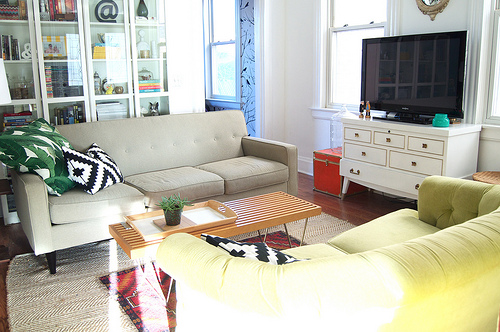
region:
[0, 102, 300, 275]
Pillows are on a couch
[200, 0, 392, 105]
Daylight coming from two windows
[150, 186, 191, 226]
A green plant in a pot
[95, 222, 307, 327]
A small rug on the floor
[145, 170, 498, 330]
A couch is lime green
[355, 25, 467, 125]
Reflections on a TV screen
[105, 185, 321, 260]
A brown wooden coffee table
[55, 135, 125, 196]
Pillow is black and white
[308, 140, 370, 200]
A red trunk on the floor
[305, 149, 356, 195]
orange trunk in the living room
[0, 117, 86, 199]
green and white throw pillow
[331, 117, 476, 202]
white dresser tv is on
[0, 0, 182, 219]
glass case shelving against the wall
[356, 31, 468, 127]
flatscreen tv with black frame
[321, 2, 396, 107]
white framed window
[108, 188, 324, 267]
coffee table between the couches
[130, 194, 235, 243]
tray on the coffee table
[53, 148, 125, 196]
black and white pillow on couch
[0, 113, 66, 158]
green and white pillow on couch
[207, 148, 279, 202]
cream seat cushion on couch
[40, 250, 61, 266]
black leg of couch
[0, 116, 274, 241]
large cream colored couch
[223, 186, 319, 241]
brown coffee table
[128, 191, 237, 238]
brown trey on table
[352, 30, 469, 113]
large tv on stand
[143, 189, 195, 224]
A plant on the tray.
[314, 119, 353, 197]
a red chest on the floor.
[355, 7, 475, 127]
Flat screen television on the stand.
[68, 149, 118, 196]
Black and white pillow on the sofa.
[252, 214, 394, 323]
Sunlight shining on the sofa.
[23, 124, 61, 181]
A green and white pillow on the sofa.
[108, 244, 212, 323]
a rug under the table.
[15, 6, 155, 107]
A glass book shelf behind the sofa.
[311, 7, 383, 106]
Sunlight shining through the window.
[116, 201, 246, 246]
A wooden tray on the table.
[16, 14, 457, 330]
living room in the photo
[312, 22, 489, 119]
television in the room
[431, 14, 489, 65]
corner of the television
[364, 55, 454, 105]
reflection in the television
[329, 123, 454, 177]
droors under the television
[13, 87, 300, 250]
couch in the photo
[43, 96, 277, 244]
light couch in photo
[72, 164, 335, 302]
table in front of couch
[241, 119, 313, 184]
arm of the couch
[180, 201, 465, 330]
light hitting the couch